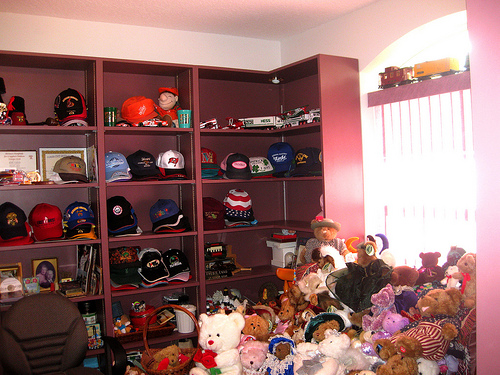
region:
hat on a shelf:
[117, 92, 157, 124]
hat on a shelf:
[26, 201, 64, 243]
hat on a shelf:
[61, 200, 98, 227]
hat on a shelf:
[99, 192, 137, 234]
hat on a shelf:
[146, 193, 183, 233]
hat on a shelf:
[220, 182, 260, 224]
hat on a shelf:
[199, 194, 230, 237]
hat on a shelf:
[194, 143, 223, 175]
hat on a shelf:
[221, 152, 259, 182]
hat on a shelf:
[244, 155, 276, 180]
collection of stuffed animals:
[188, 218, 478, 373]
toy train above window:
[377, 56, 467, 87]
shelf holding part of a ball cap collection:
[202, 137, 322, 181]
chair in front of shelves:
[5, 292, 127, 374]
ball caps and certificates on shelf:
[3, 146, 99, 183]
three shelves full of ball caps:
[109, 133, 199, 289]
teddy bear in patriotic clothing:
[372, 290, 461, 361]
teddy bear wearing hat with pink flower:
[304, 215, 346, 259]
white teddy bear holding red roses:
[191, 313, 245, 374]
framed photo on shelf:
[33, 255, 58, 290]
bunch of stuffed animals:
[172, 250, 482, 373]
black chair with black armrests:
[1, 288, 131, 373]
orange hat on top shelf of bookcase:
[119, 87, 163, 119]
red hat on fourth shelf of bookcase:
[28, 202, 66, 245]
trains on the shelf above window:
[373, 57, 475, 82]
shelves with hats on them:
[0, 39, 365, 364]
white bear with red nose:
[194, 309, 239, 373]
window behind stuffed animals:
[371, 109, 470, 254]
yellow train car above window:
[412, 55, 454, 78]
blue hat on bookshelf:
[262, 136, 299, 173]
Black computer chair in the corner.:
[0, 280, 105, 367]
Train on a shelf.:
[369, 48, 462, 90]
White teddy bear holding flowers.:
[189, 303, 246, 373]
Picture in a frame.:
[20, 253, 68, 293]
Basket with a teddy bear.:
[135, 287, 202, 368]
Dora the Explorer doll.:
[299, 305, 349, 347]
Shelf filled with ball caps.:
[2, 202, 94, 246]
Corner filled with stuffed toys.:
[256, 253, 466, 373]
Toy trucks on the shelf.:
[222, 100, 320, 135]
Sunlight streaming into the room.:
[308, 145, 465, 208]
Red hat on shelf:
[28, 202, 66, 243]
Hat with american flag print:
[217, 188, 257, 227]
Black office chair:
[0, 296, 130, 371]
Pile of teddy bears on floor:
[189, 207, 489, 374]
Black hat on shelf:
[124, 144, 159, 184]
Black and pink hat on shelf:
[218, 148, 252, 183]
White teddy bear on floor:
[187, 308, 249, 374]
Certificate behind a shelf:
[35, 142, 96, 183]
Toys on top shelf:
[198, 101, 328, 139]